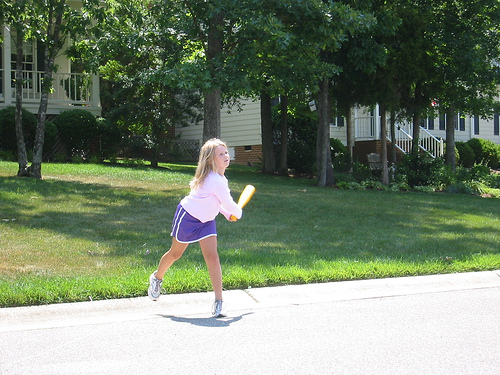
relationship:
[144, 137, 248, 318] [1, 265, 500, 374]
girl on street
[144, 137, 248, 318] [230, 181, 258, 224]
girl holds bat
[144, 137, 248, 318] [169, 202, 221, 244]
girl wears shorts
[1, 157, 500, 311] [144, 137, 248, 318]
lawn behind girl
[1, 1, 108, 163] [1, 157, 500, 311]
houses behind lawn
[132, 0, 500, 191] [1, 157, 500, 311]
houses behind lawn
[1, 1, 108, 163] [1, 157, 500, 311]
trees on lawn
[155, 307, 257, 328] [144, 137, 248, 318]
shadow of girl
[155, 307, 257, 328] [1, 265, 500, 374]
shadow on street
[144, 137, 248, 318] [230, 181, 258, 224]
girl holding bat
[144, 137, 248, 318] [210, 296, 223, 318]
girl wearing sneakers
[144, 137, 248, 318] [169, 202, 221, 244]
girl wearing shorts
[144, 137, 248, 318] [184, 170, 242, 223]
girl wearing jacket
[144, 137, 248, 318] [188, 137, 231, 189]
girl with hair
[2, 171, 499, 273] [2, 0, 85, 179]
shadow of tree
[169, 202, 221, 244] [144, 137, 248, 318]
shorts on girl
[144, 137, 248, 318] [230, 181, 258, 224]
girl swinging bat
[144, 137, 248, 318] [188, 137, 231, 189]
girl has hair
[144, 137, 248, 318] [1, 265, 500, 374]
girl in street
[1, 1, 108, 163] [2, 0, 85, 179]
houses beyond tree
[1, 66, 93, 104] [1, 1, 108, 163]
railing on houses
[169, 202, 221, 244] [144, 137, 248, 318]
shorts of girl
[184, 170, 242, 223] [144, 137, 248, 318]
jacket worn by girl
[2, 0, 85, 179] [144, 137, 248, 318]
tree behind girl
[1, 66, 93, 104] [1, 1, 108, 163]
railing of houses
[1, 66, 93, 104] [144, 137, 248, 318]
railing behind girl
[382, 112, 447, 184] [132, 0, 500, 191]
steps on houses